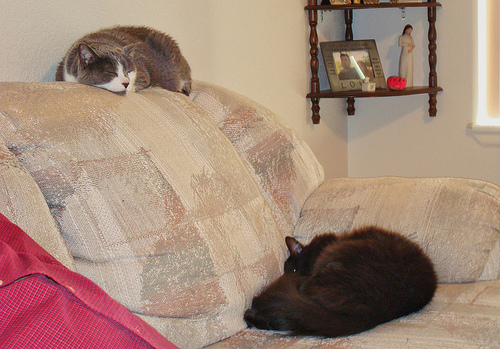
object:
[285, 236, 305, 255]
ear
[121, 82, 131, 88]
nose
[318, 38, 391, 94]
picture frame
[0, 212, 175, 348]
material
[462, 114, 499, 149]
window sill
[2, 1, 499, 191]
wall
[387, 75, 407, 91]
object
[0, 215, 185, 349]
blanket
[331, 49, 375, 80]
framed photo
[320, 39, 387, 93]
frame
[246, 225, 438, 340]
black cat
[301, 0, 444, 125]
shelf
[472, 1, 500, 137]
window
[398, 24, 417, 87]
figurine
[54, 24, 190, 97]
cat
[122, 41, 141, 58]
ear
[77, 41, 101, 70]
ear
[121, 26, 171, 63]
fur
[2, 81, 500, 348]
couch